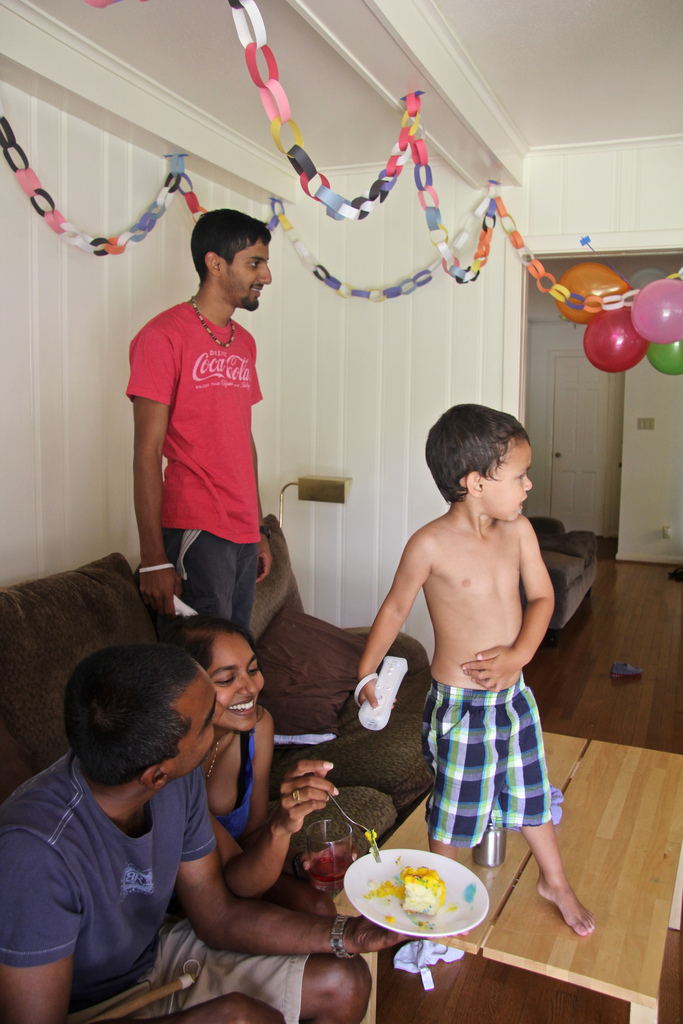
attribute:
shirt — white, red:
[123, 300, 262, 545]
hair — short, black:
[60, 644, 197, 790]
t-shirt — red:
[123, 300, 261, 544]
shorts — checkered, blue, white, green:
[422, 672, 553, 846]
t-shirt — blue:
[1, 750, 218, 1008]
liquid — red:
[312, 848, 349, 880]